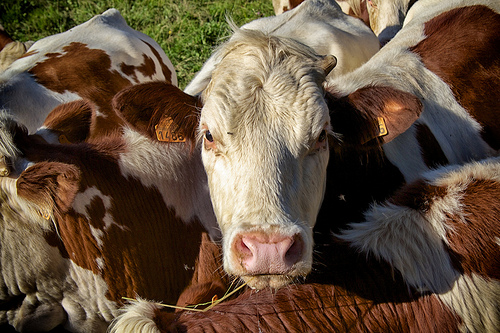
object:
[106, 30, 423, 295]
cow head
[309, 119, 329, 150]
cow eye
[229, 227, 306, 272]
cow nose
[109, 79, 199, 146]
cow ear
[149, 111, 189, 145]
yellow tag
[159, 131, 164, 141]
black numbers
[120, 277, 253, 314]
hay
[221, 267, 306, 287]
cow's mouth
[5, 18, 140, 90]
cow back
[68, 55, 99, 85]
brown/cow's skin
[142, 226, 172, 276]
brown/cow's skin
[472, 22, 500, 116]
brown/cow's skin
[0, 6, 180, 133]
cow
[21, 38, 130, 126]
skin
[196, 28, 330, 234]
fur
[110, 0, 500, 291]
cow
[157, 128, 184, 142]
writing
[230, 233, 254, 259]
nostril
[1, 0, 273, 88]
grass